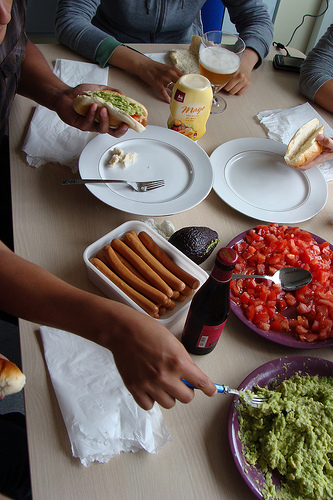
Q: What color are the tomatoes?
A: Red.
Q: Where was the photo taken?
A: The dining room.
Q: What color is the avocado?
A: Green.